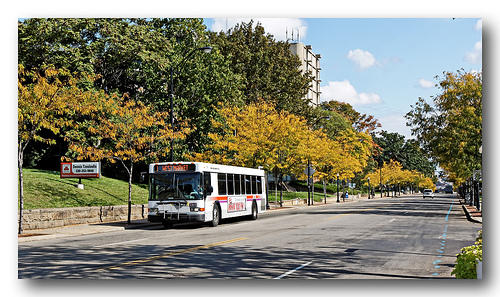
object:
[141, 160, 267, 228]
bus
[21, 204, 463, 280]
road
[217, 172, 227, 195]
windows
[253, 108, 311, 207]
trees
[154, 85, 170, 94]
leaves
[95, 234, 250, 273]
lines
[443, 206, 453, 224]
lines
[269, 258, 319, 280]
lines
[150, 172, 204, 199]
windshield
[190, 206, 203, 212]
headlight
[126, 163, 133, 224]
trunk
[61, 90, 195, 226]
tree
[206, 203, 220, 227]
wheel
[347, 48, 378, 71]
cloud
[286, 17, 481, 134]
sky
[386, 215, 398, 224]
stripe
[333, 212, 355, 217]
stripe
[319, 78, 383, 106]
clouds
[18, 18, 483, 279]
picture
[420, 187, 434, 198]
cars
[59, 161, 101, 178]
sign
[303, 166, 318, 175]
sign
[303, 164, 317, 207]
back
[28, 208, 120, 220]
wall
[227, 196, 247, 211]
ad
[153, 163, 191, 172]
board